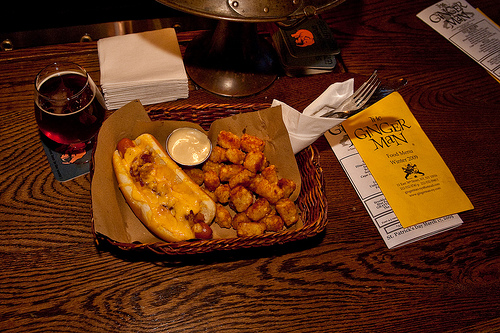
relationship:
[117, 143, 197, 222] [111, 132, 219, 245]
chilli on hotdog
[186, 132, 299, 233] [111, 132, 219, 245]
tots next to hotdog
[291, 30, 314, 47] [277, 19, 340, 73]
elephant on coaster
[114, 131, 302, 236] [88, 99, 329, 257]
food in basket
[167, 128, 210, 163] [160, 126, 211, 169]
sauce in container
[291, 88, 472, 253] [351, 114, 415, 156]
menu for restaurant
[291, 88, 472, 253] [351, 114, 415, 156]
menu for ginger man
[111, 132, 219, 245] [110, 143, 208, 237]
hotdog has cheese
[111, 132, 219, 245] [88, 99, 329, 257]
hotdog in a basket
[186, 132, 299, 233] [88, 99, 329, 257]
tots in basket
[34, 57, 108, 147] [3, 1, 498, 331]
drink on table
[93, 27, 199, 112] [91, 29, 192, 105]
napkins in a stack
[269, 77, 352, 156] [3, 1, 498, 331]
napkin on table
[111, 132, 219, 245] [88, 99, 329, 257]
hotdog in basket